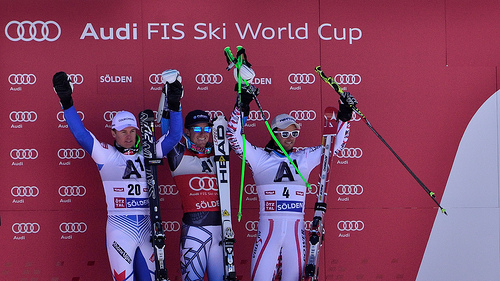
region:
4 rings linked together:
[4, 17, 71, 46]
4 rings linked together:
[5, 62, 39, 88]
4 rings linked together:
[0, 111, 42, 126]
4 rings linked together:
[10, 141, 43, 163]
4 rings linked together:
[0, 184, 43, 202]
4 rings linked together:
[4, 220, 44, 238]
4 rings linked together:
[58, 182, 90, 202]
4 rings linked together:
[58, 215, 100, 234]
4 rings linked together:
[335, 212, 374, 233]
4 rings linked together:
[334, 184, 371, 198]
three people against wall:
[45, 96, 355, 273]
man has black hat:
[181, 106, 216, 129]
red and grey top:
[172, 146, 232, 226]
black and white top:
[247, 147, 313, 218]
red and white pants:
[263, 204, 303, 277]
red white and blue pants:
[104, 207, 169, 280]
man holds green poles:
[188, 39, 293, 239]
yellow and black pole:
[318, 69, 462, 222]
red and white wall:
[1, 1, 401, 91]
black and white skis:
[119, 112, 176, 270]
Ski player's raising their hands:
[48, 67, 356, 280]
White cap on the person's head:
[113, 109, 143, 131]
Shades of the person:
[190, 123, 213, 133]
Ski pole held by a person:
[311, 64, 451, 217]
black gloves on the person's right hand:
[50, 69, 75, 111]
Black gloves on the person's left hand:
[162, 82, 184, 111]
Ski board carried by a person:
[210, 114, 243, 279]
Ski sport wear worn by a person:
[60, 104, 185, 220]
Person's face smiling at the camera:
[115, 126, 137, 147]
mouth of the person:
[124, 139, 134, 144]